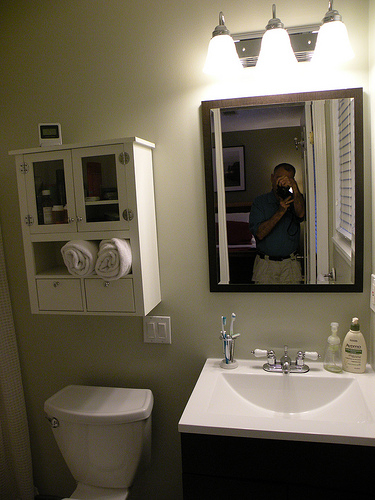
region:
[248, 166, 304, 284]
A man in the mirror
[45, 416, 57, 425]
A handle on the toilet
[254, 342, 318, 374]
A faucet on the skink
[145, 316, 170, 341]
A light switch on the wall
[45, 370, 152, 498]
A toilet in the bathroom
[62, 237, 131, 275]
Towels on the shelf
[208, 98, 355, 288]
A mirror above the sink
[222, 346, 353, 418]
A sink in the bathroom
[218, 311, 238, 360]
Toothbrushes by the sink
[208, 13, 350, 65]
Lamps above the mirror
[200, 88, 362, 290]
a mirror reflecting a man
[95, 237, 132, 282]
a towel rolled on a shelf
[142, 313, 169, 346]
light switches on a wall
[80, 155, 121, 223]
a small glass window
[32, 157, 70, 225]
a small glass window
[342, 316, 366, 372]
lotion by the sink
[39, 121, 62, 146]
a small white clock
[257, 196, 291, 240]
a man's tattooed arm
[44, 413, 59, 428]
a metal toilet flusher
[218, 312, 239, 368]
toothbrushes in a metal jar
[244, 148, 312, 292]
a guy taking a picture on a bath room mirror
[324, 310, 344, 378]
a clear bottle of hand soap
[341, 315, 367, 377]
a bottle of lotion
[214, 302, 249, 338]
two tooth brushes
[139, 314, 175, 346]
a white light switch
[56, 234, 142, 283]
two white rolled up towels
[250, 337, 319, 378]
a faucet set with white handles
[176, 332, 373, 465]
a modern white sink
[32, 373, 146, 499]
a white toilet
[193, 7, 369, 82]
a three set light fixture for bath rooms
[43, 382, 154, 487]
a white toilet tank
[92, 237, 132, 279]
a rolled up towel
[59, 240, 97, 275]
a rolled up towel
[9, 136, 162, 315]
a cabinet attached to the wall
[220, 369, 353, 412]
a white sink basin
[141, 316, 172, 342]
two white light switches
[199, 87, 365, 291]
a mirror hung on the wall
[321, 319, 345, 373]
a clear soap bottle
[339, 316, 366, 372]
a white lotion bottle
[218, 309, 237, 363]
two tooth brushes in a holder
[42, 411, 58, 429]
Metal handle to flush the toilet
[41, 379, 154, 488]
Back of a toilet against the wall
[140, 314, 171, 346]
Light switches on the wall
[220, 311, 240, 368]
Two tooth brushes and a razor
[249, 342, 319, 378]
metal sink faucet and handles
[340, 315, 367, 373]
Aveeno lotion plastic bottle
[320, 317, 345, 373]
Plastic bottle with soap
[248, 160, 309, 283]
Man taking a picture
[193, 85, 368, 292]
Mirror hanging on the wall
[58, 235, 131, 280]
Rolled up bath towels